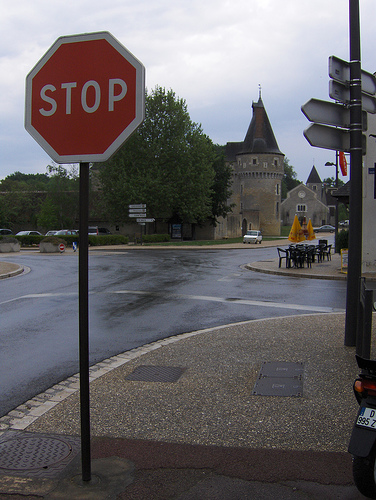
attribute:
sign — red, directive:
[24, 31, 145, 164]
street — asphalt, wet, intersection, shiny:
[2, 235, 375, 431]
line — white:
[120, 288, 350, 315]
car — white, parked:
[242, 228, 263, 245]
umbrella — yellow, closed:
[286, 213, 307, 245]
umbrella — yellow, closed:
[305, 218, 317, 241]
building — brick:
[216, 90, 285, 241]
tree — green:
[36, 175, 83, 225]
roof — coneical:
[239, 98, 284, 156]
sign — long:
[136, 216, 156, 223]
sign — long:
[128, 211, 147, 219]